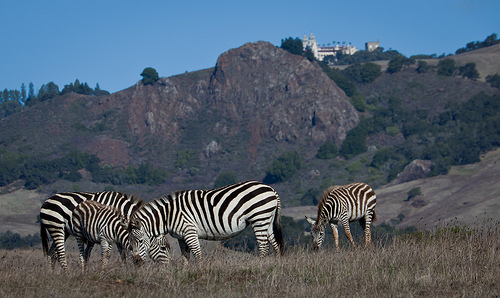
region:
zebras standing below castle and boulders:
[27, 25, 470, 278]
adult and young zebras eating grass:
[27, 165, 447, 275]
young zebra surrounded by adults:
[30, 172, 215, 272]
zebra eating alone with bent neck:
[295, 157, 405, 262]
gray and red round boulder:
[191, 21, 381, 176]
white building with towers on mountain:
[286, 15, 366, 75]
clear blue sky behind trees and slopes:
[10, 5, 207, 180]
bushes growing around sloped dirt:
[326, 50, 492, 170]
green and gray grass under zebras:
[17, 220, 483, 290]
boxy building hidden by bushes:
[356, 28, 388, 64]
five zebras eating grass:
[45, 189, 362, 268]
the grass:
[329, 251, 356, 281]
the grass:
[364, 241, 395, 296]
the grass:
[342, 239, 377, 291]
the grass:
[318, 240, 357, 297]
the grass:
[359, 243, 382, 286]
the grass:
[375, 236, 402, 288]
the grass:
[379, 278, 391, 293]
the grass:
[342, 256, 367, 285]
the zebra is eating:
[81, 171, 289, 271]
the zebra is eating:
[128, 161, 209, 219]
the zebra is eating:
[100, 168, 204, 253]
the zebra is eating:
[105, 194, 212, 295]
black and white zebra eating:
[308, 195, 391, 257]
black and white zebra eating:
[138, 192, 304, 267]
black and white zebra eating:
[81, 204, 133, 257]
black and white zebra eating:
[37, 191, 74, 274]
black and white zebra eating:
[101, 186, 135, 215]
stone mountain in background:
[207, 40, 350, 147]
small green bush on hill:
[342, 129, 364, 156]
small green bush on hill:
[273, 153, 305, 170]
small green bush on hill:
[208, 167, 238, 189]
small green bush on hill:
[136, 64, 161, 78]